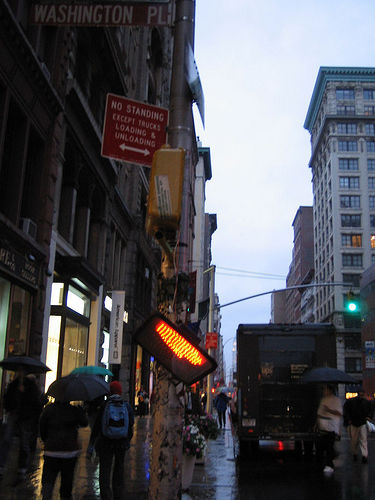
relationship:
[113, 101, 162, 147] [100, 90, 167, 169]
letters on sign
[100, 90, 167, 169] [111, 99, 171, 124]
sign says no standing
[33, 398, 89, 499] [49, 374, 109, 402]
person with an umbrella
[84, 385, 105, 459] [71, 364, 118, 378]
person with an umbrella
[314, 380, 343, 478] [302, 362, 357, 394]
pedestrian with an umbrella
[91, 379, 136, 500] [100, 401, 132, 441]
person carrying a backpack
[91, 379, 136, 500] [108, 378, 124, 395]
person wearing a hat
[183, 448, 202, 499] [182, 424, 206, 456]
pot filled with flowers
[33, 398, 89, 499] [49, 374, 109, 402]
person carrying an umbrella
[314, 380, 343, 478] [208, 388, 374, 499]
pedestrian walking on street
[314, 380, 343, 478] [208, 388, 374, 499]
pedestrian crossing street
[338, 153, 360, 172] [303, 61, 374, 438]
window on building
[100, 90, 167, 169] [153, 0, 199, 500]
sign on pole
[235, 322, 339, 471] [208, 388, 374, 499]
vehicle on street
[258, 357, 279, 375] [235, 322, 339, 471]
ups on vehicle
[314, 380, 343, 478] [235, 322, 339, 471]
pedestrian behind vehicle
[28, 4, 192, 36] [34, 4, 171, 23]
sign says washington pl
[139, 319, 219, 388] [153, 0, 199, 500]
crosswalk sign on pole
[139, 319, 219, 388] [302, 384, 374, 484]
crosswalk sign for pedestrian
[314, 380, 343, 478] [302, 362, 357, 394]
pedestrian holding an umbrella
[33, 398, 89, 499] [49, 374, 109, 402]
person holding an umbrella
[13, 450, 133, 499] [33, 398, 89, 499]
pavement near person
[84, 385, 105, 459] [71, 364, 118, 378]
person holding an umbrella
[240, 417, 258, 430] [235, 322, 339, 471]
license plate on vehicle